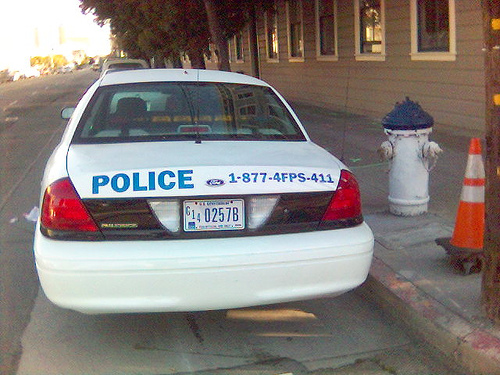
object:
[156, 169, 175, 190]
letter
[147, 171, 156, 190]
letter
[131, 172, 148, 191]
letter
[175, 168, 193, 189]
letter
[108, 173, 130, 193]
letter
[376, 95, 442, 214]
fire hydrant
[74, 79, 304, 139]
window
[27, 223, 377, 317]
bumper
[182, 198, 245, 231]
plate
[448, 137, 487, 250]
cone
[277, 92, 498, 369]
sidewalk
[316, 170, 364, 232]
light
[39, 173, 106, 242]
light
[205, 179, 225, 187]
logo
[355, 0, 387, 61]
window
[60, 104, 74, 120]
mirror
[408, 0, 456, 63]
windows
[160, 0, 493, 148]
building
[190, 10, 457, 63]
row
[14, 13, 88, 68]
light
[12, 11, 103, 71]
sky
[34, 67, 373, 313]
back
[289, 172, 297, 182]
letters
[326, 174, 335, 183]
numbers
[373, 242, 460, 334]
curb paint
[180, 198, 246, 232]
license plate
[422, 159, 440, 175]
chain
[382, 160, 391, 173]
chain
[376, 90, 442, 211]
hydrant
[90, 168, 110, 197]
letter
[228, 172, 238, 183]
number 1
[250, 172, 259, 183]
number 7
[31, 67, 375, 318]
car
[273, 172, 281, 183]
number 4